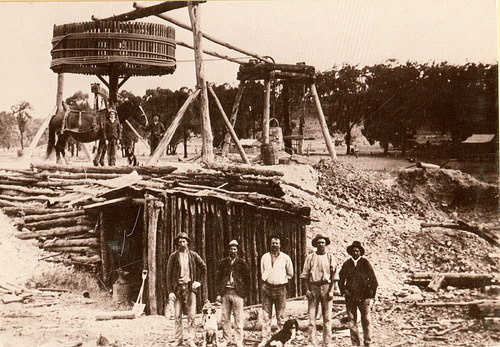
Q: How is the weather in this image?
A: It is clear.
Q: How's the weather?
A: It is clear.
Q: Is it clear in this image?
A: Yes, it is clear.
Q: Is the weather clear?
A: Yes, it is clear.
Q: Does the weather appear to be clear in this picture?
A: Yes, it is clear.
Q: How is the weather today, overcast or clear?
A: It is clear.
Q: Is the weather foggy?
A: No, it is clear.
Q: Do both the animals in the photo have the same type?
A: No, they are horses and dogs.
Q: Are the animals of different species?
A: Yes, they are horses and dogs.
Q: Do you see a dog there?
A: Yes, there is a dog.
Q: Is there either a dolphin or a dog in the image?
A: Yes, there is a dog.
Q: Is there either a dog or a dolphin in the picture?
A: Yes, there is a dog.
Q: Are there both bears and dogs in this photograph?
A: No, there is a dog but no bears.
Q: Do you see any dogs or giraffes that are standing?
A: Yes, the dog is standing.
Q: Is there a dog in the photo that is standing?
A: Yes, there is a dog that is standing.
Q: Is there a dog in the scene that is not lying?
A: Yes, there is a dog that is standing.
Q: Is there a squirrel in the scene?
A: No, there are no squirrels.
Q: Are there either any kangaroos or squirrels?
A: No, there are no squirrels or kangaroos.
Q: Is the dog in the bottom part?
A: Yes, the dog is in the bottom of the image.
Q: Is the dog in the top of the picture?
A: No, the dog is in the bottom of the image.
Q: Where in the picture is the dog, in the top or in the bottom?
A: The dog is in the bottom of the image.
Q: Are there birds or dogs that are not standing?
A: No, there is a dog but it is standing.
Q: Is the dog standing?
A: Yes, the dog is standing.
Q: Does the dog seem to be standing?
A: Yes, the dog is standing.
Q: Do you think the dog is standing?
A: Yes, the dog is standing.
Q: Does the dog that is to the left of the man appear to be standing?
A: Yes, the dog is standing.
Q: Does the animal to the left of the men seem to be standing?
A: Yes, the dog is standing.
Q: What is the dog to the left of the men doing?
A: The dog is standing.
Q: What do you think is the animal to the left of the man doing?
A: The dog is standing.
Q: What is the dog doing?
A: The dog is standing.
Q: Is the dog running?
A: No, the dog is standing.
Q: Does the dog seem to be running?
A: No, the dog is standing.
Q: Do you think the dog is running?
A: No, the dog is standing.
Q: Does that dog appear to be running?
A: No, the dog is standing.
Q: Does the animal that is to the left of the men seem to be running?
A: No, the dog is standing.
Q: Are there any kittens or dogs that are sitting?
A: No, there is a dog but it is standing.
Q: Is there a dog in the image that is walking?
A: No, there is a dog but it is standing.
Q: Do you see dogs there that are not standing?
A: No, there is a dog but it is standing.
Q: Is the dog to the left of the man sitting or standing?
A: The dog is standing.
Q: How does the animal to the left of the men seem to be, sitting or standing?
A: The dog is standing.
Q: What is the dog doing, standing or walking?
A: The dog is standing.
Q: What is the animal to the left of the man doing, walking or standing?
A: The dog is standing.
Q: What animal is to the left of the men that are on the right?
A: The animal is a dog.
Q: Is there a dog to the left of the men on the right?
A: Yes, there is a dog to the left of the men.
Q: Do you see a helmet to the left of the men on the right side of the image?
A: No, there is a dog to the left of the men.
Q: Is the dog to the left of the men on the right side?
A: Yes, the dog is to the left of the men.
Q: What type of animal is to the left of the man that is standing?
A: The animal is a dog.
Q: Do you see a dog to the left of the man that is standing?
A: Yes, there is a dog to the left of the man.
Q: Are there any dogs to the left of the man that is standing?
A: Yes, there is a dog to the left of the man.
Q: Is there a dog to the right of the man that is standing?
A: No, the dog is to the left of the man.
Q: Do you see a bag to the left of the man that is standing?
A: No, there is a dog to the left of the man.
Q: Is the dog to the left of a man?
A: Yes, the dog is to the left of a man.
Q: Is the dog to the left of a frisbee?
A: No, the dog is to the left of a man.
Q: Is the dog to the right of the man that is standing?
A: No, the dog is to the left of the man.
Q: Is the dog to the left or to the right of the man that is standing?
A: The dog is to the left of the man.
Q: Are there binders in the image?
A: No, there are no binders.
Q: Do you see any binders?
A: No, there are no binders.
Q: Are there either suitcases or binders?
A: No, there are no binders or suitcases.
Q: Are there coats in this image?
A: Yes, there is a coat.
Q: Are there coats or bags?
A: Yes, there is a coat.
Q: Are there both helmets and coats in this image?
A: No, there is a coat but no helmets.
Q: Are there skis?
A: No, there are no skis.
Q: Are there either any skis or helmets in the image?
A: No, there are no skis or helmets.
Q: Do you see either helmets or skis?
A: No, there are no skis or helmets.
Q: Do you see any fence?
A: No, there are no fences.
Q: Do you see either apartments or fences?
A: No, there are no fences or apartments.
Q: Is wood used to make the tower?
A: Yes, the tower is made of wood.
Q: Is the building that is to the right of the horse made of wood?
A: Yes, the tower is made of wood.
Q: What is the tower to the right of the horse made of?
A: The tower is made of wood.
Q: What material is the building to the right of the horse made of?
A: The tower is made of wood.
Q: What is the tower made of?
A: The tower is made of wood.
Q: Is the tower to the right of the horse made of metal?
A: No, the tower is made of wood.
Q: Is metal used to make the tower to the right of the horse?
A: No, the tower is made of wood.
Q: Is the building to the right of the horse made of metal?
A: No, the tower is made of wood.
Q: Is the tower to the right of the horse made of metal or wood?
A: The tower is made of wood.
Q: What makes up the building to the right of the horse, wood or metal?
A: The tower is made of wood.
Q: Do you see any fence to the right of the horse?
A: No, there is a tower to the right of the horse.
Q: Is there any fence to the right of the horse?
A: No, there is a tower to the right of the horse.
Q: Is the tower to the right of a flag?
A: No, the tower is to the right of the horse.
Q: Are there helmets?
A: No, there are no helmets.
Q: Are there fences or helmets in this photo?
A: No, there are no helmets or fences.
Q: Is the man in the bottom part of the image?
A: Yes, the man is in the bottom of the image.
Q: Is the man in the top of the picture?
A: No, the man is in the bottom of the image.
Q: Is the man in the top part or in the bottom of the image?
A: The man is in the bottom of the image.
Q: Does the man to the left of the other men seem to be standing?
A: Yes, the man is standing.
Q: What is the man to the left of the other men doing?
A: The man is standing.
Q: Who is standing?
A: The man is standing.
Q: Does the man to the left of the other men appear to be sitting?
A: No, the man is standing.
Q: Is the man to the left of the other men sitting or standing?
A: The man is standing.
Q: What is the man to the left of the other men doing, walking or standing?
A: The man is standing.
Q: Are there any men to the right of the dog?
A: Yes, there is a man to the right of the dog.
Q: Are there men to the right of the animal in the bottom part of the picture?
A: Yes, there is a man to the right of the dog.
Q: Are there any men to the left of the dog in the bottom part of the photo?
A: No, the man is to the right of the dog.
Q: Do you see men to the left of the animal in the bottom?
A: No, the man is to the right of the dog.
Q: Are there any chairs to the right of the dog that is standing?
A: No, there is a man to the right of the dog.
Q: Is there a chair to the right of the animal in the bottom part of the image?
A: No, there is a man to the right of the dog.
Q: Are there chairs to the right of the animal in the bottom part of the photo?
A: No, there is a man to the right of the dog.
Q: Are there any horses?
A: Yes, there is a horse.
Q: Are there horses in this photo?
A: Yes, there is a horse.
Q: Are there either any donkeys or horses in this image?
A: Yes, there is a horse.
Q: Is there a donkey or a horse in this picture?
A: Yes, there is a horse.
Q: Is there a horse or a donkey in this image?
A: Yes, there is a horse.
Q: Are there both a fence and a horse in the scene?
A: No, there is a horse but no fences.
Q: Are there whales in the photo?
A: No, there are no whales.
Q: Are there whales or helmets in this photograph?
A: No, there are no whales or helmets.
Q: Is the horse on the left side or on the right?
A: The horse is on the left of the image.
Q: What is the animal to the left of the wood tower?
A: The animal is a horse.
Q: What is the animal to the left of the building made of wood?
A: The animal is a horse.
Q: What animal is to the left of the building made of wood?
A: The animal is a horse.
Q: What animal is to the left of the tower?
A: The animal is a horse.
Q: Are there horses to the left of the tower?
A: Yes, there is a horse to the left of the tower.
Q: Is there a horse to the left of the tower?
A: Yes, there is a horse to the left of the tower.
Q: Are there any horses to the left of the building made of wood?
A: Yes, there is a horse to the left of the tower.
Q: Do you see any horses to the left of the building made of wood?
A: Yes, there is a horse to the left of the tower.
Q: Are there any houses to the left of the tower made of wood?
A: No, there is a horse to the left of the tower.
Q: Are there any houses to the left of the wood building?
A: No, there is a horse to the left of the tower.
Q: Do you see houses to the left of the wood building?
A: No, there is a horse to the left of the tower.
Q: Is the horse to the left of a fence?
A: No, the horse is to the left of the tower.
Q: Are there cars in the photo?
A: No, there are no cars.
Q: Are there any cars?
A: No, there are no cars.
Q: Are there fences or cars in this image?
A: No, there are no cars or fences.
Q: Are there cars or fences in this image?
A: No, there are no cars or fences.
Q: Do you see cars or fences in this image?
A: No, there are no cars or fences.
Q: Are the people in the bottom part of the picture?
A: Yes, the people are in the bottom of the image.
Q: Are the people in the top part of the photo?
A: No, the people are in the bottom of the image.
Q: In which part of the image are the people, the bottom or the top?
A: The people are in the bottom of the image.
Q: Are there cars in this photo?
A: No, there are no cars.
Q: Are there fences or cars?
A: No, there are no cars or fences.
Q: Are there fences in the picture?
A: No, there are no fences.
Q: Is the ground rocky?
A: Yes, the ground is rocky.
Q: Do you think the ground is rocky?
A: Yes, the ground is rocky.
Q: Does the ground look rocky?
A: Yes, the ground is rocky.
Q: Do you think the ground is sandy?
A: No, the ground is rocky.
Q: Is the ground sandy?
A: No, the ground is rocky.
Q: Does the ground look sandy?
A: No, the ground is rocky.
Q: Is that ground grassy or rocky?
A: The ground is rocky.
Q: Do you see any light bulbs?
A: No, there are no light bulbs.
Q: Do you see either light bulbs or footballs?
A: No, there are no light bulbs or footballs.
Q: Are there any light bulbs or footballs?
A: No, there are no light bulbs or footballs.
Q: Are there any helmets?
A: No, there are no helmets.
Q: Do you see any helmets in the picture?
A: No, there are no helmets.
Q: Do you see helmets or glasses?
A: No, there are no helmets or glasses.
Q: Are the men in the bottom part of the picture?
A: Yes, the men are in the bottom of the image.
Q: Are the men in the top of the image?
A: No, the men are in the bottom of the image.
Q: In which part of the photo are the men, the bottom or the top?
A: The men are in the bottom of the image.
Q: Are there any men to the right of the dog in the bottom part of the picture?
A: Yes, there are men to the right of the dog.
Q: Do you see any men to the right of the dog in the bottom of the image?
A: Yes, there are men to the right of the dog.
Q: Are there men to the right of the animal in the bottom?
A: Yes, there are men to the right of the dog.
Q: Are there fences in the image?
A: No, there are no fences.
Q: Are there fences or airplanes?
A: No, there are no fences or airplanes.